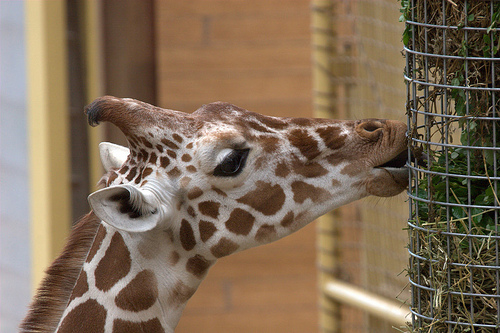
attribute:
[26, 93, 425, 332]
giraffe — feeding , large, brown, spotted, long, white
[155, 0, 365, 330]
wall — blurred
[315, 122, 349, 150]
spot — brown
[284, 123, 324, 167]
spot — brown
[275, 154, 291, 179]
spot — brown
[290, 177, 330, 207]
spot — brown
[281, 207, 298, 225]
spot — brown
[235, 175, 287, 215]
spot — brown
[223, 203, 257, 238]
spot — brown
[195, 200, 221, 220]
spot — brown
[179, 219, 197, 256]
spot — brown 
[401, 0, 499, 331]
container — large, wired, metal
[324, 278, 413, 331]
pole — long, thick, metal, round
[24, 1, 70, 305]
paint — tall, long, yellow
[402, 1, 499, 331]
wire — large, silver, metal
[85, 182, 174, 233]
ear — large, white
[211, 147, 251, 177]
eye — large, almond, black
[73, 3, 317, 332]
door — large, tall, open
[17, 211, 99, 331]
hair — long, short, brown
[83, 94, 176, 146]
horn — short, round, bone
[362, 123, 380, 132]
hole — small, round